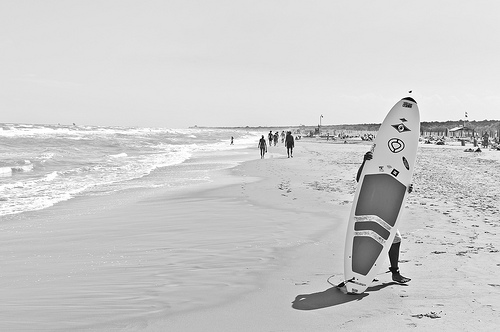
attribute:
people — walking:
[281, 131, 299, 160]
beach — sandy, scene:
[0, 125, 499, 331]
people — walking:
[256, 134, 270, 160]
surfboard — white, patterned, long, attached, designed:
[340, 87, 427, 301]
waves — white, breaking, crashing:
[5, 123, 219, 137]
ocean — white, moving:
[1, 119, 267, 225]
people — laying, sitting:
[473, 146, 483, 156]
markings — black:
[391, 120, 414, 134]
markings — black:
[400, 114, 410, 122]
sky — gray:
[1, 1, 500, 133]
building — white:
[449, 124, 478, 140]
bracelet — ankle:
[388, 264, 403, 273]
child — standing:
[228, 132, 237, 149]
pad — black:
[348, 169, 410, 292]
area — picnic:
[449, 132, 480, 142]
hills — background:
[314, 116, 499, 136]